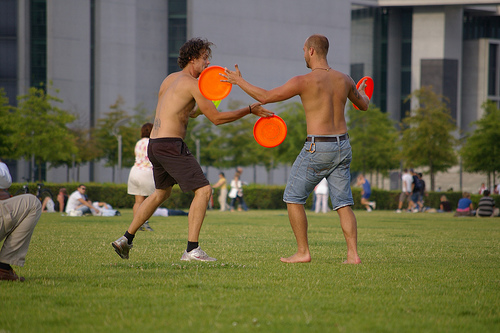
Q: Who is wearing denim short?
A: Man on the right.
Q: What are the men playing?
A: Frisbee.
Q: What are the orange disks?
A: Frisbees.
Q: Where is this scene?
A: Park.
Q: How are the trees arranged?
A: In a row.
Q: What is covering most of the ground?
A: Grass.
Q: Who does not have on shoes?
A: Man on the right.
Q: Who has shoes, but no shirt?
A: Man on the left.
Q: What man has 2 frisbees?
A: The barefoot man.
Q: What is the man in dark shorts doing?
A: Throwing a frisbee.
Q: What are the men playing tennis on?
A: The grass.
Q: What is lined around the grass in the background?
A: Bushes.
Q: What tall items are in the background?
A: Trees.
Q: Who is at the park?
A: A bunch of people.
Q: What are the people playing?
A: Frisbee.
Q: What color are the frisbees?
A: Orange.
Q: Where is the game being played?
A: Park.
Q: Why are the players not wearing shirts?
A: Hot.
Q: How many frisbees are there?
A: Three.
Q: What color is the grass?
A: Green.